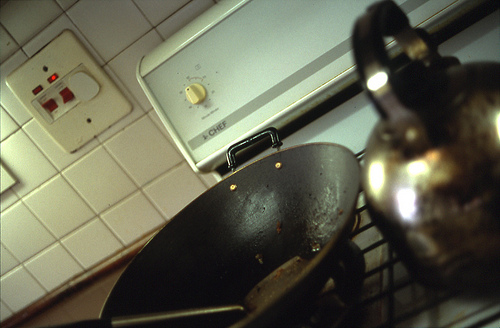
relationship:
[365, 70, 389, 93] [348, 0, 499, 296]
light reflected on kettle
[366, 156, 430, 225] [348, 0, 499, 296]
light reflected on kettle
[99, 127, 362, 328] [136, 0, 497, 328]
pan on top of stove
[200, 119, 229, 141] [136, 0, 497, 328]
brand name on front of stove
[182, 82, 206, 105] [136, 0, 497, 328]
knob on back part of stove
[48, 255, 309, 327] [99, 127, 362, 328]
spatula inside of pan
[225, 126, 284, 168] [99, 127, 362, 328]
handle on side of pan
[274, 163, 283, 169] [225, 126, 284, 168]
screw holding handle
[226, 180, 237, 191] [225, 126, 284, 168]
screw holding handle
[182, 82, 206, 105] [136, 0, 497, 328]
knob to regulate stove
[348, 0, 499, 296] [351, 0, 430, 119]
kettle has handle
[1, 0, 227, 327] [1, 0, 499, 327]
wall inside of kitchen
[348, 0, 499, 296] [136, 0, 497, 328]
kettle on top of stove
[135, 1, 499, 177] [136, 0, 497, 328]
back panel on back of stove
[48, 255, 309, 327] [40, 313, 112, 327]
spatula has handle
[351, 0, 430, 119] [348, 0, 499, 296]
handle on top of kettle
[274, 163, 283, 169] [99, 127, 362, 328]
screw inside of pan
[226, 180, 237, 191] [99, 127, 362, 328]
screw inside of pan